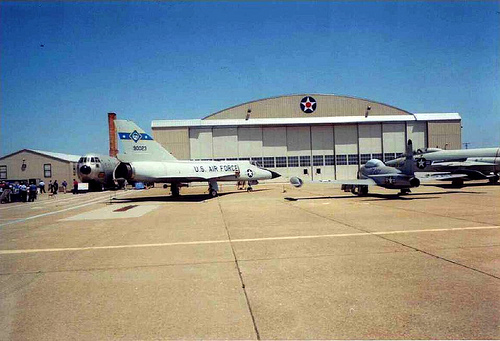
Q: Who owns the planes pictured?
A: U.S. Air Force.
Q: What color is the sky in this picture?
A: Blue.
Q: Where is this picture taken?
A: An Airplane hangar.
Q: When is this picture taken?
A: Daytime.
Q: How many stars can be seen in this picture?
A: Three.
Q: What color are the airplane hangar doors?
A: Grey.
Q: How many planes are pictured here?
A: Four.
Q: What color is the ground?
A: Tan.